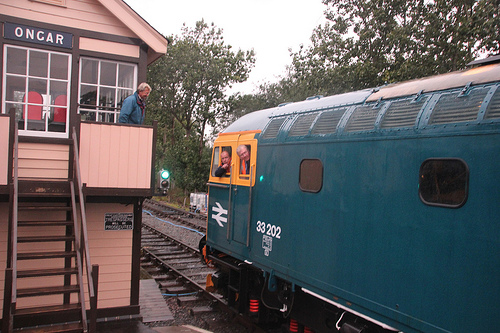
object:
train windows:
[210, 148, 222, 178]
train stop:
[0, 0, 168, 332]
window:
[234, 143, 254, 179]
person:
[211, 145, 233, 178]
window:
[412, 160, 467, 209]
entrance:
[14, 98, 86, 327]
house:
[1, 0, 173, 332]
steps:
[18, 235, 81, 243]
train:
[204, 53, 500, 333]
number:
[275, 224, 282, 239]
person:
[113, 83, 156, 122]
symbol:
[259, 233, 275, 255]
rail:
[137, 221, 241, 311]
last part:
[204, 95, 323, 315]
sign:
[8, 19, 73, 49]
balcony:
[78, 121, 161, 198]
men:
[235, 144, 252, 178]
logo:
[205, 200, 231, 229]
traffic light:
[156, 165, 173, 200]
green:
[157, 169, 172, 182]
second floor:
[0, 0, 178, 197]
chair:
[18, 88, 45, 131]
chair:
[49, 92, 69, 131]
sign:
[101, 212, 137, 232]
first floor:
[0, 193, 145, 332]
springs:
[244, 300, 258, 315]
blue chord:
[142, 207, 203, 237]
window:
[297, 158, 325, 194]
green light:
[257, 174, 265, 183]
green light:
[158, 171, 170, 181]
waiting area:
[3, 46, 135, 145]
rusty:
[142, 216, 203, 286]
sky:
[121, 0, 498, 155]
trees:
[141, 0, 499, 192]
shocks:
[243, 278, 325, 331]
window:
[50, 55, 73, 80]